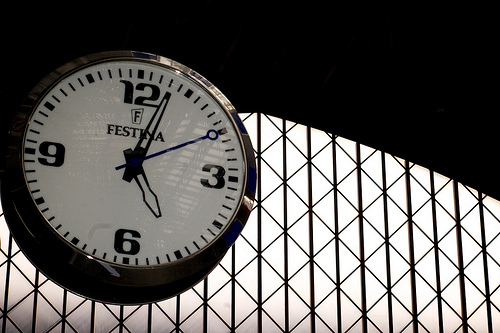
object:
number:
[112, 228, 141, 256]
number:
[37, 141, 66, 168]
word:
[105, 123, 166, 143]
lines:
[25, 182, 77, 231]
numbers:
[197, 163, 227, 189]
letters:
[113, 126, 123, 137]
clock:
[4, 49, 262, 307]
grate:
[224, 140, 423, 311]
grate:
[240, 142, 466, 329]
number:
[117, 78, 162, 108]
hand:
[122, 147, 161, 218]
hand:
[112, 130, 217, 172]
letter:
[129, 109, 142, 125]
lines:
[2, 102, 499, 333]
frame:
[1, 51, 258, 306]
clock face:
[18, 60, 250, 269]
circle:
[206, 128, 219, 140]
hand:
[120, 91, 175, 183]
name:
[104, 123, 165, 143]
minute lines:
[42, 193, 105, 265]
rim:
[1, 51, 254, 309]